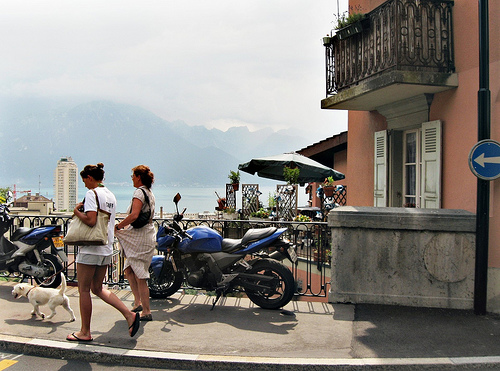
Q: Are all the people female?
A: Yes, all the people are female.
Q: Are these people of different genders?
A: No, all the people are female.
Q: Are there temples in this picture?
A: No, there are no temples.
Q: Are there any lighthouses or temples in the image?
A: No, there are no temples or lighthouses.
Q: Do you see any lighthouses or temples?
A: No, there are no temples or lighthouses.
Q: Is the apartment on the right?
A: Yes, the apartment is on the right of the image.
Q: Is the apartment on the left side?
A: No, the apartment is on the right of the image.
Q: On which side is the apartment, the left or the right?
A: The apartment is on the right of the image.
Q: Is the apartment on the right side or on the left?
A: The apartment is on the right of the image.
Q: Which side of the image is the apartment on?
A: The apartment is on the right of the image.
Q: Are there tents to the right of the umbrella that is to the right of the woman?
A: No, there is an apartment to the right of the umbrella.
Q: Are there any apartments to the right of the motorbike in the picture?
A: Yes, there is an apartment to the right of the motorbike.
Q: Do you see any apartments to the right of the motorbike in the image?
A: Yes, there is an apartment to the right of the motorbike.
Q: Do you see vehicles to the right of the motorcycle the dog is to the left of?
A: No, there is an apartment to the right of the motorcycle.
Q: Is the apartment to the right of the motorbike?
A: Yes, the apartment is to the right of the motorbike.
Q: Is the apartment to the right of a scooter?
A: No, the apartment is to the right of the motorbike.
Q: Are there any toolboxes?
A: No, there are no toolboxes.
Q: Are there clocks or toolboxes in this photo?
A: No, there are no toolboxes or clocks.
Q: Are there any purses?
A: Yes, there is a purse.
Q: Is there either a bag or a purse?
A: Yes, there is a purse.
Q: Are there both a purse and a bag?
A: Yes, there are both a purse and a bag.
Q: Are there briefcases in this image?
A: No, there are no briefcases.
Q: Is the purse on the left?
A: Yes, the purse is on the left of the image.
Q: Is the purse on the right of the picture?
A: No, the purse is on the left of the image.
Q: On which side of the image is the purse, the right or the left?
A: The purse is on the left of the image.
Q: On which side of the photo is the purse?
A: The purse is on the left of the image.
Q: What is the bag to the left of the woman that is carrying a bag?
A: The bag is a purse.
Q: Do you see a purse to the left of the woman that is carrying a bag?
A: Yes, there is a purse to the left of the woman.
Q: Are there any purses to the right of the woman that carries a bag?
A: No, the purse is to the left of the woman.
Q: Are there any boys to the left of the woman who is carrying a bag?
A: No, there is a purse to the left of the woman.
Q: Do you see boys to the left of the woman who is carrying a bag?
A: No, there is a purse to the left of the woman.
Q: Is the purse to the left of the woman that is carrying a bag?
A: Yes, the purse is to the left of the woman.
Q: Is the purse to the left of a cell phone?
A: No, the purse is to the left of the woman.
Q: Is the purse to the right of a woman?
A: No, the purse is to the left of a woman.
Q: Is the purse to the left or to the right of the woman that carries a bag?
A: The purse is to the left of the woman.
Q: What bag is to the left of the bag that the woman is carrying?
A: The bag is a purse.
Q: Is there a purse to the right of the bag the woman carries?
A: No, the purse is to the left of the bag.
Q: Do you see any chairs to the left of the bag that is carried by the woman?
A: No, there is a purse to the left of the bag.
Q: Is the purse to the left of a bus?
A: No, the purse is to the left of the bag.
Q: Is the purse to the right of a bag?
A: No, the purse is to the left of a bag.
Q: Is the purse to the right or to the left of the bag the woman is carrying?
A: The purse is to the left of the bag.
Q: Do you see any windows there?
A: Yes, there is a window.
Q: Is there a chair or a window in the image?
A: Yes, there is a window.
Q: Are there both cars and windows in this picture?
A: No, there is a window but no cars.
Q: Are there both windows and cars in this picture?
A: No, there is a window but no cars.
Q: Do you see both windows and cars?
A: No, there is a window but no cars.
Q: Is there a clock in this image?
A: No, there are no clocks.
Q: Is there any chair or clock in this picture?
A: No, there are no clocks or chairs.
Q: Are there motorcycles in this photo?
A: Yes, there is a motorcycle.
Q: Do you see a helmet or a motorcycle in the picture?
A: Yes, there is a motorcycle.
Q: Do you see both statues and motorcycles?
A: No, there is a motorcycle but no statues.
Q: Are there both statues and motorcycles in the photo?
A: No, there is a motorcycle but no statues.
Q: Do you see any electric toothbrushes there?
A: No, there are no electric toothbrushes.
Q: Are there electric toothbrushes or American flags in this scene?
A: No, there are no electric toothbrushes or American flags.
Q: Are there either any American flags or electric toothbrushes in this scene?
A: No, there are no electric toothbrushes or American flags.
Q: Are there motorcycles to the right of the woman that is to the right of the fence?
A: Yes, there is a motorcycle to the right of the woman.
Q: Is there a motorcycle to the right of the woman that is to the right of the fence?
A: Yes, there is a motorcycle to the right of the woman.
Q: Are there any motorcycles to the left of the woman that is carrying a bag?
A: No, the motorcycle is to the right of the woman.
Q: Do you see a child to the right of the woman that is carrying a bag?
A: No, there is a motorcycle to the right of the woman.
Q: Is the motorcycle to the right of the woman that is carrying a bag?
A: Yes, the motorcycle is to the right of the woman.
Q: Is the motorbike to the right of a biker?
A: No, the motorbike is to the right of the woman.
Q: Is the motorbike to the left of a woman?
A: No, the motorbike is to the right of a woman.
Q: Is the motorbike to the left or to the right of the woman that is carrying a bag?
A: The motorbike is to the right of the woman.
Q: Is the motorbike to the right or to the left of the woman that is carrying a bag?
A: The motorbike is to the right of the woman.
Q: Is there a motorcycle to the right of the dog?
A: Yes, there is a motorcycle to the right of the dog.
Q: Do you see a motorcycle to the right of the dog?
A: Yes, there is a motorcycle to the right of the dog.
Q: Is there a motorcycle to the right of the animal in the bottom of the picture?
A: Yes, there is a motorcycle to the right of the dog.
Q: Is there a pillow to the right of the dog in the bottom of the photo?
A: No, there is a motorcycle to the right of the dog.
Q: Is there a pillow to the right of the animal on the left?
A: No, there is a motorcycle to the right of the dog.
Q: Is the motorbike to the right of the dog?
A: Yes, the motorbike is to the right of the dog.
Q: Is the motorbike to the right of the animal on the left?
A: Yes, the motorbike is to the right of the dog.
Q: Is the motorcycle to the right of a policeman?
A: No, the motorcycle is to the right of the dog.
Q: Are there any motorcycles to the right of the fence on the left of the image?
A: Yes, there is a motorcycle to the right of the fence.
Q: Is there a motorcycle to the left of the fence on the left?
A: No, the motorcycle is to the right of the fence.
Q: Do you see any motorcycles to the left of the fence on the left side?
A: No, the motorcycle is to the right of the fence.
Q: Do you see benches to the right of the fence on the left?
A: No, there is a motorcycle to the right of the fence.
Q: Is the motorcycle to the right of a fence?
A: Yes, the motorcycle is to the right of a fence.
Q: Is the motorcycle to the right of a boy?
A: No, the motorcycle is to the right of a fence.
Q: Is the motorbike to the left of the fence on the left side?
A: No, the motorbike is to the right of the fence.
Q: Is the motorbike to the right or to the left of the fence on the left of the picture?
A: The motorbike is to the right of the fence.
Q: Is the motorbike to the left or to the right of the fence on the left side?
A: The motorbike is to the right of the fence.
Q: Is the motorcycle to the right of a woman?
A: Yes, the motorcycle is to the right of a woman.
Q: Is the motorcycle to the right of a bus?
A: No, the motorcycle is to the right of a woman.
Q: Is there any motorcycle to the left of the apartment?
A: Yes, there is a motorcycle to the left of the apartment.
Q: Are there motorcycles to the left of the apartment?
A: Yes, there is a motorcycle to the left of the apartment.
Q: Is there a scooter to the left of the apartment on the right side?
A: No, there is a motorcycle to the left of the apartment.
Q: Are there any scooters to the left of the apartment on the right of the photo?
A: No, there is a motorcycle to the left of the apartment.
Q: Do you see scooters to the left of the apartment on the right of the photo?
A: No, there is a motorcycle to the left of the apartment.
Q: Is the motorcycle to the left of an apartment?
A: Yes, the motorcycle is to the left of an apartment.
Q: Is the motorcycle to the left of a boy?
A: No, the motorcycle is to the left of an apartment.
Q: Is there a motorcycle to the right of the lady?
A: Yes, there is a motorcycle to the right of the lady.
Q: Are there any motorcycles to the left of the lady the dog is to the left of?
A: No, the motorcycle is to the right of the lady.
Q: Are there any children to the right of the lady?
A: No, there is a motorcycle to the right of the lady.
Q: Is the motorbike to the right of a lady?
A: Yes, the motorbike is to the right of a lady.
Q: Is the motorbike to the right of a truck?
A: No, the motorbike is to the right of a lady.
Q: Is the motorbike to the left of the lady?
A: No, the motorbike is to the right of the lady.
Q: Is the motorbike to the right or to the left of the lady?
A: The motorbike is to the right of the lady.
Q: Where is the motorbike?
A: The motorbike is on the sidewalk.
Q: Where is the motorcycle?
A: The motorbike is on the sidewalk.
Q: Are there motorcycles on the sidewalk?
A: Yes, there is a motorcycle on the sidewalk.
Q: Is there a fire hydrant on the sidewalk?
A: No, there is a motorcycle on the sidewalk.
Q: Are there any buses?
A: No, there are no buses.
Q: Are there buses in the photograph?
A: No, there are no buses.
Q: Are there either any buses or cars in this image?
A: No, there are no buses or cars.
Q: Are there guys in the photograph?
A: No, there are no guys.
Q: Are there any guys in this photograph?
A: No, there are no guys.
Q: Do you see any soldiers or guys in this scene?
A: No, there are no guys or soldiers.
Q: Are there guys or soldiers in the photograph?
A: No, there are no guys or soldiers.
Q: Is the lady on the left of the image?
A: Yes, the lady is on the left of the image.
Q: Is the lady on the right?
A: No, the lady is on the left of the image.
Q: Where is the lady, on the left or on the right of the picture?
A: The lady is on the left of the image.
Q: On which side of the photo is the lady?
A: The lady is on the left of the image.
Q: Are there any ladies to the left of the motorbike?
A: Yes, there is a lady to the left of the motorbike.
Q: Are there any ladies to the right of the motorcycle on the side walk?
A: No, the lady is to the left of the motorcycle.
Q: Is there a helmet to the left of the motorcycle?
A: No, there is a lady to the left of the motorcycle.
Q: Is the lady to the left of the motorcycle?
A: Yes, the lady is to the left of the motorcycle.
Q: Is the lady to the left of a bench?
A: No, the lady is to the left of the motorcycle.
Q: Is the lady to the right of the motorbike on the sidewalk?
A: No, the lady is to the left of the motorbike.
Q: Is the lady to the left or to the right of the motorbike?
A: The lady is to the left of the motorbike.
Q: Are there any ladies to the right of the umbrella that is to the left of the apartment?
A: No, the lady is to the left of the umbrella.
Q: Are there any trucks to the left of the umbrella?
A: No, there is a lady to the left of the umbrella.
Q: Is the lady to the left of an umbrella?
A: Yes, the lady is to the left of an umbrella.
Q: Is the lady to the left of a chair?
A: No, the lady is to the left of an umbrella.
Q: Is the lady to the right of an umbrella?
A: No, the lady is to the left of an umbrella.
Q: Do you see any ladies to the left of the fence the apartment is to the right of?
A: Yes, there is a lady to the left of the fence.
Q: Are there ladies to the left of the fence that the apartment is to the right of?
A: Yes, there is a lady to the left of the fence.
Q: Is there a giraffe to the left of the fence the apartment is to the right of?
A: No, there is a lady to the left of the fence.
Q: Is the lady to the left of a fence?
A: Yes, the lady is to the left of a fence.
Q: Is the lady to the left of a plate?
A: No, the lady is to the left of a fence.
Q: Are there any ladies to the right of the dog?
A: Yes, there is a lady to the right of the dog.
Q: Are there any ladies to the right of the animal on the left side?
A: Yes, there is a lady to the right of the dog.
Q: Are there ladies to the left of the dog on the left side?
A: No, the lady is to the right of the dog.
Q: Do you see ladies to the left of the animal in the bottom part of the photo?
A: No, the lady is to the right of the dog.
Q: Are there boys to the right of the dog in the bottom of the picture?
A: No, there is a lady to the right of the dog.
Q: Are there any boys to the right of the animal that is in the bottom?
A: No, there is a lady to the right of the dog.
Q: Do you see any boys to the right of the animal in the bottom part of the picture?
A: No, there is a lady to the right of the dog.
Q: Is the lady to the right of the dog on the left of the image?
A: Yes, the lady is to the right of the dog.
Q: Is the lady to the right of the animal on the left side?
A: Yes, the lady is to the right of the dog.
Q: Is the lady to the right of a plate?
A: No, the lady is to the right of the dog.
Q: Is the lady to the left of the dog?
A: No, the lady is to the right of the dog.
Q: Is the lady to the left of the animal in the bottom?
A: No, the lady is to the right of the dog.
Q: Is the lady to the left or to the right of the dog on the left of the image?
A: The lady is to the right of the dog.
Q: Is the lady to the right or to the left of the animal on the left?
A: The lady is to the right of the dog.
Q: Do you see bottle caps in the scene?
A: No, there are no bottle caps.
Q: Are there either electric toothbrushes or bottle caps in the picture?
A: No, there are no bottle caps or electric toothbrushes.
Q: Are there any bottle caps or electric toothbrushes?
A: No, there are no bottle caps or electric toothbrushes.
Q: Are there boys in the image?
A: No, there are no boys.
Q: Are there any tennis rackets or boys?
A: No, there are no boys or tennis rackets.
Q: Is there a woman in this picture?
A: Yes, there is a woman.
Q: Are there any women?
A: Yes, there is a woman.